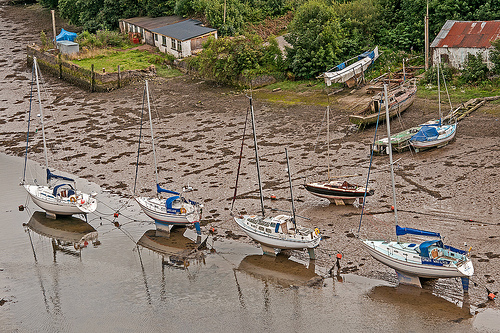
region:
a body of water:
[49, 265, 80, 296]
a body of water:
[95, 276, 132, 314]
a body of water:
[70, 301, 106, 331]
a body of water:
[137, 300, 170, 331]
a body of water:
[183, 297, 227, 329]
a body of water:
[228, 305, 249, 331]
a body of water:
[265, 289, 296, 323]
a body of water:
[300, 300, 328, 325]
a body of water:
[357, 318, 374, 325]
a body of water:
[387, 308, 404, 329]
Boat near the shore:
[116, 75, 206, 236]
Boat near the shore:
[10, 50, 95, 240]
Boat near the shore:
[225, 94, 318, 276]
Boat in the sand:
[302, 118, 372, 210]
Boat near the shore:
[350, 208, 494, 324]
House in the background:
[425, 11, 498, 79]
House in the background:
[112, 7, 220, 68]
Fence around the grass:
[25, 36, 136, 103]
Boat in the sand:
[401, 102, 463, 164]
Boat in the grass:
[317, 31, 387, 99]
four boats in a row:
[21, 53, 468, 293]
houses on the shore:
[116, 4, 490, 87]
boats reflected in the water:
[26, 209, 466, 320]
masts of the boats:
[26, 37, 452, 242]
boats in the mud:
[308, 64, 468, 152]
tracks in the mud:
[13, 50, 479, 270]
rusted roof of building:
[437, 15, 497, 52]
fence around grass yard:
[22, 42, 140, 85]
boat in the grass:
[310, 42, 382, 91]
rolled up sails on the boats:
[35, 167, 438, 240]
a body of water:
[27, 280, 54, 307]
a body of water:
[38, 312, 65, 331]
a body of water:
[2, 304, 31, 329]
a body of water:
[102, 280, 129, 303]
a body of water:
[148, 303, 176, 318]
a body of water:
[175, 300, 210, 320]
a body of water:
[217, 306, 236, 322]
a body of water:
[249, 303, 272, 320]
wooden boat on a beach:
[336, 54, 426, 131]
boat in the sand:
[299, 103, 367, 210]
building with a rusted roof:
[428, 12, 498, 82]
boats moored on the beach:
[23, 51, 498, 318]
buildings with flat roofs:
[110, 11, 227, 62]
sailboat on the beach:
[130, 77, 217, 247]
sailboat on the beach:
[356, 89, 466, 297]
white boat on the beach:
[227, 97, 322, 274]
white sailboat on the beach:
[15, 52, 112, 240]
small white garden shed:
[55, 39, 85, 58]